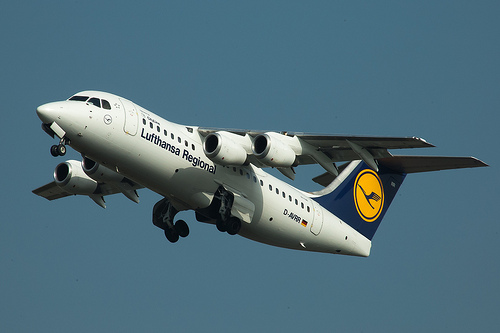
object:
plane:
[30, 89, 488, 258]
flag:
[346, 169, 386, 221]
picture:
[357, 182, 381, 209]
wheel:
[167, 219, 190, 246]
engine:
[203, 132, 249, 167]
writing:
[139, 128, 217, 175]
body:
[109, 124, 279, 227]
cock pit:
[51, 89, 113, 142]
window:
[143, 119, 196, 151]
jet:
[203, 129, 303, 179]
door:
[120, 99, 140, 135]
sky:
[0, 0, 500, 86]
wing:
[299, 134, 437, 164]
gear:
[165, 217, 241, 244]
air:
[281, 0, 492, 109]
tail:
[311, 153, 487, 190]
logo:
[352, 168, 385, 223]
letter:
[141, 127, 217, 176]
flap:
[289, 133, 436, 171]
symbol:
[353, 167, 386, 222]